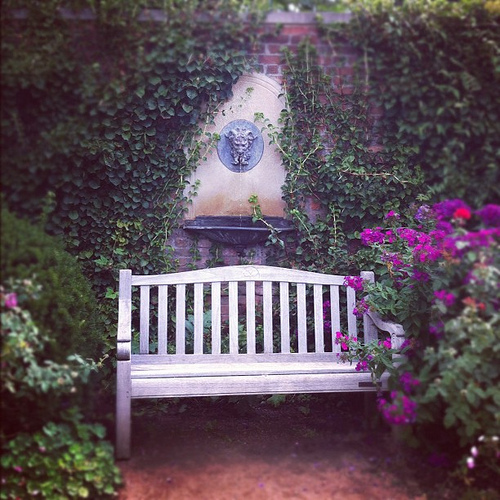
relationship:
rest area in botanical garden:
[113, 268, 403, 459] [352, 198, 498, 443]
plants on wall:
[0, 0, 270, 306] [0, 8, 397, 337]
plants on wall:
[78, 60, 183, 239] [63, 27, 458, 226]